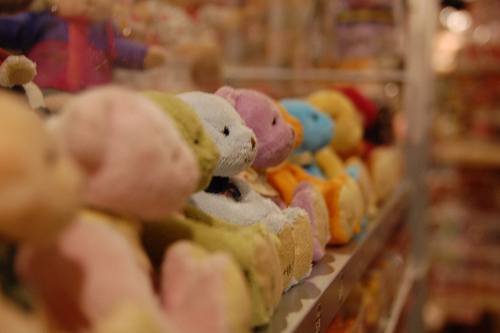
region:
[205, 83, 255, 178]
White teddy bear face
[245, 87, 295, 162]
Pink teddy bear face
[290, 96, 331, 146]
Blue teddy bear face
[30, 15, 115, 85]
Pink suspenders and tie on teddy bear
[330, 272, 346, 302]
Black and white price tag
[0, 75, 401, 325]
A line of different colored teddy bears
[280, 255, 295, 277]
Letter written on the teddy bear foot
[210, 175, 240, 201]
Black tie on teddy bear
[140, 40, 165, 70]
The paw of the teddy bear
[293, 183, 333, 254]
Pink and white teddy bear foot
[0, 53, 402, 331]
Row of various colors of stuffed animals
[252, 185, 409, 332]
Shelf holding stuffed animals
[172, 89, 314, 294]
White stuffed animal with blue scarf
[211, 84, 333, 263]
Purple stuffed toy with brown on bottom of feet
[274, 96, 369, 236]
Bright blue teddy bear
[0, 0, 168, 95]
Doll or stuffed animal wearing purple and pink jacket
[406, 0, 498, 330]
Very blurred area that looks like shop entrance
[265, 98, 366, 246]
Carrot colored stuffed animal slightly out of line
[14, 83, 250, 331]
Soft, furry stuffed animal colored light pink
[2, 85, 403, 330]
Shelf full of colorful, cuddly stuffed toys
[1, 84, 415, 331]
Row of teddy bears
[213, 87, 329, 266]
Pink teddy bear in the middle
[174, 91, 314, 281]
White teddy bear in the middle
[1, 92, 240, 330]
Teddy bears out of focus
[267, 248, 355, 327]
Shadows of teddy bears' feet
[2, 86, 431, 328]
Toy shop shelves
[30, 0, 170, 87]
Doll out of focus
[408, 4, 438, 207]
Metal bar in background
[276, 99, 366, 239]
Blue teddy bear out of focus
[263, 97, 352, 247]
Partially hidden orange teddy bear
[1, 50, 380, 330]
Row of small teddy bears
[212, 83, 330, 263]
Pink teddy bear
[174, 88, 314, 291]
White teddy bear with a scarf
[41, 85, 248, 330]
Baby pink teddy bear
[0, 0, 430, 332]
Teddy bears on a shelf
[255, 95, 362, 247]
Orange teddy bear sitting on a shelf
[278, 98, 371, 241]
Blue teddy bear sitting on a shelf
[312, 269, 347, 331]
Sticker on a shelf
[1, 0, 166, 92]
Teddy bear wearing a purple and pink jacket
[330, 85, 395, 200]
Red teddy bear with brown feet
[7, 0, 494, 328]
Shelves in a toy store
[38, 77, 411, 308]
A row of teddy bears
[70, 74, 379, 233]
Multicolored teddy bears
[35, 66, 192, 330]
A pink teddy bear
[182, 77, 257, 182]
A white teddy bear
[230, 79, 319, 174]
A pink teddy bear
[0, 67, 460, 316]
Many soft teddy bears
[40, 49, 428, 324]
Teddy bear collection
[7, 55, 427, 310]
Stuffed bears for sale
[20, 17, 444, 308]
Stuffed bears on a shelf